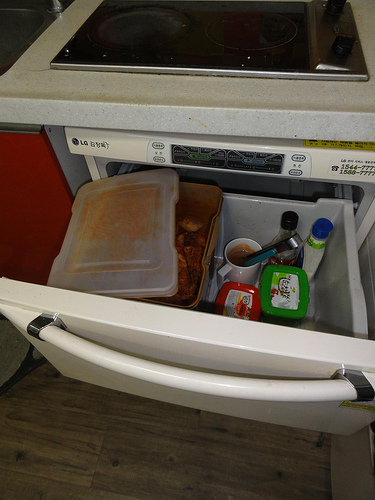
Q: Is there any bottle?
A: Yes, there is a bottle.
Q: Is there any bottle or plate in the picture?
A: Yes, there is a bottle.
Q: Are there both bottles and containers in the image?
A: Yes, there are both a bottle and a container.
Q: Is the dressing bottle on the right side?
A: Yes, the bottle is on the right of the image.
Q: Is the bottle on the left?
A: No, the bottle is on the right of the image.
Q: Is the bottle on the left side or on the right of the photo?
A: The bottle is on the right of the image.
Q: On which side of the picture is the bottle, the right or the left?
A: The bottle is on the right of the image.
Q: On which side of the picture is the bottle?
A: The bottle is on the right of the image.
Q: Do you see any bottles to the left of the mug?
A: No, the bottle is to the right of the mug.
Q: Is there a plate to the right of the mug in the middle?
A: No, there is a bottle to the right of the mug.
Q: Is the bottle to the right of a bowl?
A: No, the bottle is to the right of the mug.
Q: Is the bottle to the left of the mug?
A: No, the bottle is to the right of the mug.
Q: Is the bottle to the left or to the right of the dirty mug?
A: The bottle is to the right of the mug.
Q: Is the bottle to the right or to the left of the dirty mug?
A: The bottle is to the right of the mug.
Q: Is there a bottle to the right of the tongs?
A: Yes, there is a bottle to the right of the tongs.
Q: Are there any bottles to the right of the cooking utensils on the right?
A: Yes, there is a bottle to the right of the tongs.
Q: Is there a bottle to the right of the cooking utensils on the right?
A: Yes, there is a bottle to the right of the tongs.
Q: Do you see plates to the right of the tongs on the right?
A: No, there is a bottle to the right of the tongs.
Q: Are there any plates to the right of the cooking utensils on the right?
A: No, there is a bottle to the right of the tongs.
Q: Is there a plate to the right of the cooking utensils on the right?
A: No, there is a bottle to the right of the tongs.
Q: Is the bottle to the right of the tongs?
A: Yes, the bottle is to the right of the tongs.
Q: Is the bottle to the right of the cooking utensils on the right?
A: Yes, the bottle is to the right of the tongs.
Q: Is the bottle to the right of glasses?
A: No, the bottle is to the right of the tongs.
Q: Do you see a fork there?
A: No, there are no forks.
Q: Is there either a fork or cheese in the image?
A: No, there are no forks or cheese.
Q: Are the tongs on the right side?
A: Yes, the tongs are on the right of the image.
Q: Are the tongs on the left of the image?
A: No, the tongs are on the right of the image.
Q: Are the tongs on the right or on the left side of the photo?
A: The tongs are on the right of the image.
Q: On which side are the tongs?
A: The tongs are on the right of the image.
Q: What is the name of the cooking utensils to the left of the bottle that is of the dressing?
A: The cooking utensils are tongs.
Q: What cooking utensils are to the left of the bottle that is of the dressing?
A: The cooking utensils are tongs.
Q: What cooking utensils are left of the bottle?
A: The cooking utensils are tongs.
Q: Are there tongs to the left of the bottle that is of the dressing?
A: Yes, there are tongs to the left of the bottle.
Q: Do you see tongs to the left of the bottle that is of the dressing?
A: Yes, there are tongs to the left of the bottle.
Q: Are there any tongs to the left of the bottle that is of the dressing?
A: Yes, there are tongs to the left of the bottle.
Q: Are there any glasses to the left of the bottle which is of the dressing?
A: No, there are tongs to the left of the bottle.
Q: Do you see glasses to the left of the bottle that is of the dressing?
A: No, there are tongs to the left of the bottle.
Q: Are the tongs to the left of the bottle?
A: Yes, the tongs are to the left of the bottle.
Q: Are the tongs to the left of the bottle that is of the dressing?
A: Yes, the tongs are to the left of the bottle.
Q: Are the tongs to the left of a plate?
A: No, the tongs are to the left of the bottle.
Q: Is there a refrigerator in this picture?
A: Yes, there is a refrigerator.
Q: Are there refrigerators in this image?
A: Yes, there is a refrigerator.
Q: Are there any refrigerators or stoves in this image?
A: Yes, there is a refrigerator.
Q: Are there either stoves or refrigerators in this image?
A: Yes, there is a refrigerator.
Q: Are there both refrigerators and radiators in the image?
A: No, there is a refrigerator but no radiators.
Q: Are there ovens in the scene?
A: No, there are no ovens.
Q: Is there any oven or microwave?
A: No, there are no ovens or microwaves.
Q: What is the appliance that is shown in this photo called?
A: The appliance is a refrigerator.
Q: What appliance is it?
A: The appliance is a refrigerator.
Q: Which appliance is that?
A: This is a refrigerator.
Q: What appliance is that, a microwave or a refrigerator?
A: This is a refrigerator.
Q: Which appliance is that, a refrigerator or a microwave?
A: This is a refrigerator.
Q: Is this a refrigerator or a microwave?
A: This is a refrigerator.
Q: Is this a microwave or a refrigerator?
A: This is a refrigerator.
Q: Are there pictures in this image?
A: No, there are no pictures.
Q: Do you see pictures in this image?
A: No, there are no pictures.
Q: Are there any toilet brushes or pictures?
A: No, there are no pictures or toilet brushes.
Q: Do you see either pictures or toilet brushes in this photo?
A: No, there are no pictures or toilet brushes.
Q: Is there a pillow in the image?
A: No, there are no pillows.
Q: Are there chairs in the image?
A: No, there are no chairs.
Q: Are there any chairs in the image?
A: No, there are no chairs.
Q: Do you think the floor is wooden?
A: Yes, the floor is wooden.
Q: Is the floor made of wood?
A: Yes, the floor is made of wood.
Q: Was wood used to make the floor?
A: Yes, the floor is made of wood.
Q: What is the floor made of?
A: The floor is made of wood.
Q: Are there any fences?
A: No, there are no fences.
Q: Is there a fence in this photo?
A: No, there are no fences.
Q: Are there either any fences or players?
A: No, there are no fences or players.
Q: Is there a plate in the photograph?
A: No, there are no plates.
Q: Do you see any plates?
A: No, there are no plates.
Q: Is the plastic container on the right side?
A: Yes, the container is on the right of the image.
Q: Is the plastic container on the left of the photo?
A: No, the container is on the right of the image.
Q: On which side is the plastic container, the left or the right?
A: The container is on the right of the image.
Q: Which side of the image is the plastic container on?
A: The container is on the right of the image.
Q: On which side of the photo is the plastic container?
A: The container is on the right of the image.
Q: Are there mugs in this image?
A: Yes, there is a mug.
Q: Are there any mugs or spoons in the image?
A: Yes, there is a mug.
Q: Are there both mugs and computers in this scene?
A: No, there is a mug but no computers.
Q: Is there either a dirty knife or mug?
A: Yes, there is a dirty mug.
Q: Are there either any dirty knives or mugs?
A: Yes, there is a dirty mug.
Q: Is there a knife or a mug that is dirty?
A: Yes, the mug is dirty.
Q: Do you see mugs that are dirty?
A: Yes, there is a dirty mug.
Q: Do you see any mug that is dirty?
A: Yes, there is a mug that is dirty.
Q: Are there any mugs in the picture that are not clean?
A: Yes, there is a dirty mug.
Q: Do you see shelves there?
A: No, there are no shelves.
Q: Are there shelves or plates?
A: No, there are no shelves or plates.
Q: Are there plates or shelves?
A: No, there are no shelves or plates.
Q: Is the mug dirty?
A: Yes, the mug is dirty.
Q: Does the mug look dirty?
A: Yes, the mug is dirty.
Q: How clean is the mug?
A: The mug is dirty.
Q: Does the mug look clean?
A: No, the mug is dirty.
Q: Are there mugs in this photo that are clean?
A: No, there is a mug but it is dirty.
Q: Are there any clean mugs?
A: No, there is a mug but it is dirty.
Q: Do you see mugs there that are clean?
A: No, there is a mug but it is dirty.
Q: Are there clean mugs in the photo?
A: No, there is a mug but it is dirty.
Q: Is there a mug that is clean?
A: No, there is a mug but it is dirty.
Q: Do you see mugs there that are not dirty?
A: No, there is a mug but it is dirty.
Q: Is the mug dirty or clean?
A: The mug is dirty.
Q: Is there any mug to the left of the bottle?
A: Yes, there is a mug to the left of the bottle.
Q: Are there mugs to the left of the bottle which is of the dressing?
A: Yes, there is a mug to the left of the bottle.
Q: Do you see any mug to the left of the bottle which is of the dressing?
A: Yes, there is a mug to the left of the bottle.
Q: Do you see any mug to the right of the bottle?
A: No, the mug is to the left of the bottle.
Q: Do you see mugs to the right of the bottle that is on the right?
A: No, the mug is to the left of the bottle.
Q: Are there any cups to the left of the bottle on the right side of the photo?
A: No, there is a mug to the left of the bottle.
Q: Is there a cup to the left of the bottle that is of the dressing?
A: No, there is a mug to the left of the bottle.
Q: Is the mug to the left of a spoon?
A: No, the mug is to the left of the bottle.